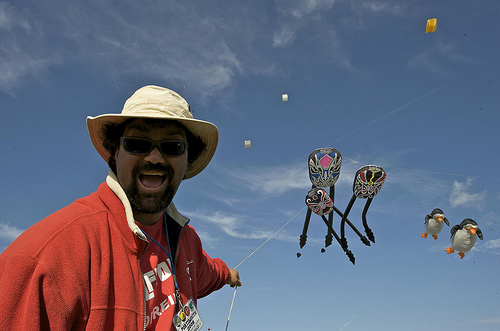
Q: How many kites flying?
A: Eight.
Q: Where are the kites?
A: In the sky.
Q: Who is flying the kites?
A: The man.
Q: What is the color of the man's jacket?
A: Orange.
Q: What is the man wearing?
A: A jacket.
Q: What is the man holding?
A: Kites.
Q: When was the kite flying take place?
A: Daytime.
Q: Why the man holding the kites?
A: To fly kites.